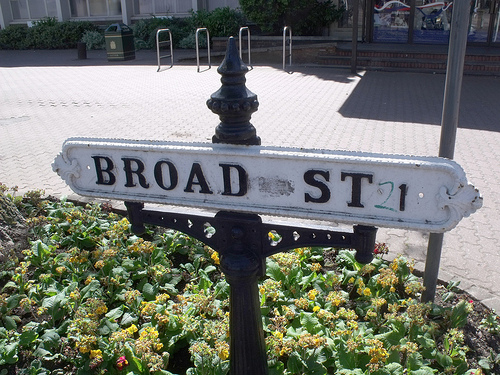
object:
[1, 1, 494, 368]
daytime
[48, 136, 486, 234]
board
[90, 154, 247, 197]
black lettering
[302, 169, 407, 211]
black lettering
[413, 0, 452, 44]
window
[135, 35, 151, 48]
shrubs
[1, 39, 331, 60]
planter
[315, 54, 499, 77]
steps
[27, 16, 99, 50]
bush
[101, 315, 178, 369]
flowers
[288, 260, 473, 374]
flowers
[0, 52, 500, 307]
drive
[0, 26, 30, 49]
plant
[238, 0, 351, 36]
plant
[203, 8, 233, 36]
plant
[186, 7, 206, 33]
plant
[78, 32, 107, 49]
plant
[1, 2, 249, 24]
wall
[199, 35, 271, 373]
pole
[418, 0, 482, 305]
pole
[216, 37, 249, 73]
top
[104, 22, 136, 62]
dustbin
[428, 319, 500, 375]
plant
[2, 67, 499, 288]
pathway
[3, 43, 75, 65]
concrete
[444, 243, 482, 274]
bricks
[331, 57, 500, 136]
shadow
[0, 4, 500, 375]
picture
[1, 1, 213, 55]
building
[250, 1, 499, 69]
building